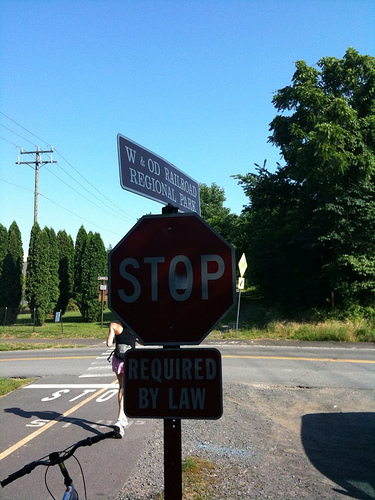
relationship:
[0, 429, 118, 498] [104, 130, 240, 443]
bike at sign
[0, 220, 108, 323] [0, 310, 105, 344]
trees on a corner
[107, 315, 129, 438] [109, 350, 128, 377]
girl wearing shorts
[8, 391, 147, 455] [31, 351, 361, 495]
shadow on ground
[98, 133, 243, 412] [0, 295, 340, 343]
sign in a yard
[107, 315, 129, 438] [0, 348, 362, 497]
girl on ground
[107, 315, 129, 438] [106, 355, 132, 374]
girl in shorts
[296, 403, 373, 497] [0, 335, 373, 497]
shadow on road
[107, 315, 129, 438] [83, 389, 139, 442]
girl wearing shoe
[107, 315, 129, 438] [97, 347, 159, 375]
girl wearing shorts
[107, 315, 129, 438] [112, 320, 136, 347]
girl wears tank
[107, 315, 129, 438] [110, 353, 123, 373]
girl wears shorts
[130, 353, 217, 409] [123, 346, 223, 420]
writing on sign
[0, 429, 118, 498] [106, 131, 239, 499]
bike near sign